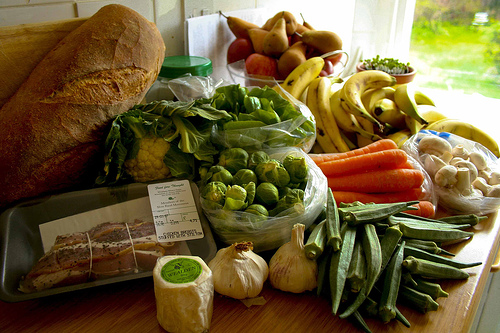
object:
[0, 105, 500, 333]
table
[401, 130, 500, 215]
bag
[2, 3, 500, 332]
food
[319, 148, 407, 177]
carrots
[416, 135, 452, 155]
mushrooms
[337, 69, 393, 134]
bananas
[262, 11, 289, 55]
pears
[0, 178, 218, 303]
tray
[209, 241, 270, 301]
garlic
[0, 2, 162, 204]
bread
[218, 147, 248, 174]
brussel sprouts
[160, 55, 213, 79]
jar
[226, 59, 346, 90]
bowl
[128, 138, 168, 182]
cauliflower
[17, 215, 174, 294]
roll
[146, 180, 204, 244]
tag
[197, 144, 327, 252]
bag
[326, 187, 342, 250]
okra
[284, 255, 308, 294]
clove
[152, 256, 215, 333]
cheese